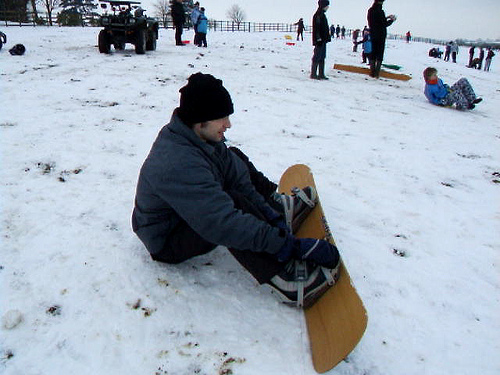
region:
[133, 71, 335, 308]
person on the snow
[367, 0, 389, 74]
person on the snow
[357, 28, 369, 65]
person on the snow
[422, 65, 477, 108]
person on the snow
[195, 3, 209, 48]
person on the snow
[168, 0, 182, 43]
person on the snow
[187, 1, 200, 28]
person on the snow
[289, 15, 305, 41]
person on the snow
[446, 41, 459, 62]
person on the snow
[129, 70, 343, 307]
a male sitting in the snow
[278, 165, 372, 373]
a wooden snow board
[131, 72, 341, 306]
a boy wearing blue gloves with a gray stripe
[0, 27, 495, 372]
a snow covered ground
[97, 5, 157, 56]
a parked green colored ATV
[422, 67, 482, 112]
a person laying in the snow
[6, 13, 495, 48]
a fence at the edge of the hill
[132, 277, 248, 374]
dirt showing through the snow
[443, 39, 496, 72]
a group of people standing in the snow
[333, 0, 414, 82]
a person standing beside a brown snowboard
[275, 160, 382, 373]
the board strapped on the mans feet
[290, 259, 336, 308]
the straps of the boots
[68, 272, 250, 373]
the grass under the snow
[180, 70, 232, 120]
the black cap on the head of the man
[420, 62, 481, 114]
the person lying in the snow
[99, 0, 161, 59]
the four wheeler in the snowy field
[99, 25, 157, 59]
the tires of the four wheelers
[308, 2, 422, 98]
the people on the snowy hill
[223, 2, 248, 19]
the tree top behind the fence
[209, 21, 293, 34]
the fence along the top of the hill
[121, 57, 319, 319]
a man sitting on the snow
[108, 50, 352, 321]
a man sitting on the snow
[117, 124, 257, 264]
the jacket is gray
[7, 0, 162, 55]
trucks on top of slope divided by railing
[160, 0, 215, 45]
adult and children standing together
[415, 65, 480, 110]
person sliding down snow with knees bent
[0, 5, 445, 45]
long fencing on top of hill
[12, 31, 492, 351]
snow-covered ground with small dark holes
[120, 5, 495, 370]
people standing and sitting on slope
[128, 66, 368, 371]
young man seated with snowboard strapped to feet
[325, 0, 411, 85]
wooden object between adult and child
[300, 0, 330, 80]
person standing and looking ahead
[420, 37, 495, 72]
group of people standing and sitting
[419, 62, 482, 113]
person on white snow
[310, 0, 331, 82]
person on white snow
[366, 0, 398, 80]
person on white snow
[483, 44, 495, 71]
person on white snow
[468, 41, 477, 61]
person on white snow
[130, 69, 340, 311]
a man sitting on the snow with a snowboard on his feet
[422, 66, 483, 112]
a person reclining in the snow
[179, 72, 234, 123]
the black hat on the man's head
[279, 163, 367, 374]
the snowboard attached to the man's feet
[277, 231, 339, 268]
the glove on the man's right hand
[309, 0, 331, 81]
a person standing on the snow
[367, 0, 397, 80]
a person standing on the snow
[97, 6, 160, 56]
a vehicle parked on the snow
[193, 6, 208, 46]
a person wearing a blue jacket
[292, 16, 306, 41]
a person standing with an outstretched arm